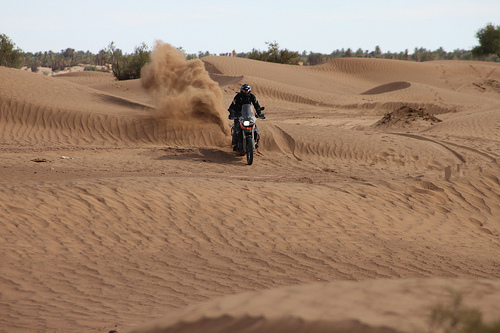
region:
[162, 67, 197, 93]
Sand kicked into the air by motorbike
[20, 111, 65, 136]
A raised sand bank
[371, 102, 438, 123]
A dark mound of sand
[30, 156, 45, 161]
A dark spot on the sand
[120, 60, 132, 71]
Plants growing in the sand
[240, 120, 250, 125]
The motorbikes bright headlamp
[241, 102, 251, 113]
The motorbikes protective screen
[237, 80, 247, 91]
A safety helmet on the head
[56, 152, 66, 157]
A whitish object on the sand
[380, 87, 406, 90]
Shadow cast on a sandbank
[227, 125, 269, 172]
front wheel of bike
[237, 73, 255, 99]
helmet of the biker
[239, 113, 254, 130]
front headlight of bike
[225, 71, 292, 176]
biker on a motorcycle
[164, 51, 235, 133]
dust of sand from bike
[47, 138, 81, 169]
random object in the sand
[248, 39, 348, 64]
trees in the back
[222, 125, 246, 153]
back wheel of bike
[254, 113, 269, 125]
side view mirror of bike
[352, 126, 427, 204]
prints of the sand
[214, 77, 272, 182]
A man riding a dirt bike.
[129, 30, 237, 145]
dirty kicked up behind a motorcycle.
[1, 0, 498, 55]
a section of hazy blue sky.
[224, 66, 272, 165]
a man racing on a dirt bike track.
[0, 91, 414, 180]
a patch of tracked covered dirt.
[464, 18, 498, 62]
a large leaf filled tree.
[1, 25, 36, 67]
a tree with lots of green leaves.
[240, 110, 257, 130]
a headlight on a motorcycle.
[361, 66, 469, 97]
a small sand hill.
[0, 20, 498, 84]
a tree filled forest.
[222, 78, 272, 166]
motorcycle on the beach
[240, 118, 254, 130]
headlight on motorcycle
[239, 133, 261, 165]
tire of a motorcycle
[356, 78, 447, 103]
dune on a beach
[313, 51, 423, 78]
dune on a beach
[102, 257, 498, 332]
dune on a beach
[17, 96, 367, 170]
dune on a beach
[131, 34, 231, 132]
plume of sand behind motorcycle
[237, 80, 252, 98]
black plastic helmet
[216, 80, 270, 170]
motorcycle being ridden on the beach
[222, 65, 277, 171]
a motorcyclist on a truck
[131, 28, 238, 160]
dust in the air behind the motorcyclist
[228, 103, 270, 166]
headlight of motorcycle is on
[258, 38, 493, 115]
a dunes formed on the sand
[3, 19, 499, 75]
green trees behind a field of sand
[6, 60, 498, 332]
a field cover with sand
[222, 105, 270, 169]
motorcycle is color black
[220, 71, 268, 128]
motorcyclist wears black helmet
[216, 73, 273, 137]
man wears black cloths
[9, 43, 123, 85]
homes near the tress